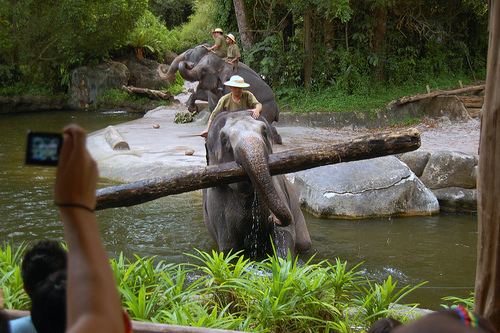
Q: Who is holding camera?
A: A girl.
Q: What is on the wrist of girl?
A: A band.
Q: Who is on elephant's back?
A: A rider.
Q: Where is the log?
A: Elephant's trunk.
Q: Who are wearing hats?
A: Riders.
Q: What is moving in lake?
A: Elephants.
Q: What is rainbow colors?
A: Wristband.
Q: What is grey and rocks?
A: Flat land.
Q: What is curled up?
A: Elephant's trunk.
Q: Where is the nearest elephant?
A: In the water.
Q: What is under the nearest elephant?
A: The water.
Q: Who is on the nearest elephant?
A: A rider.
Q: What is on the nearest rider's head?
A: A hat.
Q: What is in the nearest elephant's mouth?
A: A log.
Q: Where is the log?
A: In the nearest elephant's mouth.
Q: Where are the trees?
A: Behind the river.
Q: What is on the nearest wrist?
A: A black bracelet.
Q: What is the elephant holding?
A: A log.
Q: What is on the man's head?
A: A hat.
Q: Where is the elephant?
A: In the water.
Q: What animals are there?
A: Elephant.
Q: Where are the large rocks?
A: In the water.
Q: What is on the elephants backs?
A: The man.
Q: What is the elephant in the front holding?
A: A log.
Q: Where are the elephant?
A: In the water.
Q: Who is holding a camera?
A: The man.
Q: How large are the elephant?
A: Very large.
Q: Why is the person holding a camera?
A: To take a photo.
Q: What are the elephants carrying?
A: A log.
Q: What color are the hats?
A: Tan.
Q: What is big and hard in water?
A: Rocks.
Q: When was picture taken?
A: Daytime.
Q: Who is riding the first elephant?
A: A man.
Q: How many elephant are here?
A: Three.